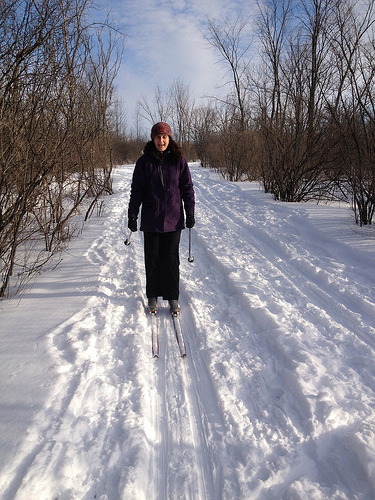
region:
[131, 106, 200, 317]
skier wearing black outfit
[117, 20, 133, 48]
white clouds in blue sky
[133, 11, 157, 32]
white clouds in blue sky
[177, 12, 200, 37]
white clouds in blue sky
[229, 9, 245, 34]
white clouds in blue sky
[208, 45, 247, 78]
white clouds in blue sky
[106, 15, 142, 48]
white clouds in blue sky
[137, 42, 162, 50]
white clouds in blue sky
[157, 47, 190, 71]
white clouds in blue sky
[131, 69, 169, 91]
white clouds in blue sky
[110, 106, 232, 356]
the woman is skiing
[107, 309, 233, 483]
lines are in the snow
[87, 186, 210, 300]
the woman is holding ski sticks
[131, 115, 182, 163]
the woman is smiling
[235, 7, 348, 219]
the trees are bare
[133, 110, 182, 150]
woman is wearing a hat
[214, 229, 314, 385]
foot prints in the snow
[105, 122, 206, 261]
the woman is wearing a coat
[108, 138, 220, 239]
the coat is purple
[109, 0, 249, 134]
the sky is partly cloudy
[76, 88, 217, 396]
a woman on skis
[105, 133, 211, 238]
a purple winter jacket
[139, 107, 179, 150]
a hat on her head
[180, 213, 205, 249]
black gloves on hands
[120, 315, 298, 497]
ski marks in the snow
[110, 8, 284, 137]
white clouds in the sky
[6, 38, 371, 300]
lots of bare trees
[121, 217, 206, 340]
black pants on woman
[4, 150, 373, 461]
snow covers the ground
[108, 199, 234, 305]
a ski pole in each hand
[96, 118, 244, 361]
This is a woman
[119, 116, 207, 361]
The woman is on skis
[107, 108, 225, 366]
The woman is skiing on snow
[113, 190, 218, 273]
She is holding ski poles in both hands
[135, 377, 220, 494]
There are ski tracks in the snow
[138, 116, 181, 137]
The woman is wearing a hat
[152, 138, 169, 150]
The woman's mouth is open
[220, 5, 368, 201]
The trees are brown and bare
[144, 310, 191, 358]
The skis are covered in snow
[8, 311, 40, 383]
This snow is untouched by people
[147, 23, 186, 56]
white clouds in blue sky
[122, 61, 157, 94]
white clouds in blue sky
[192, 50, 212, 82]
white clouds in blue sky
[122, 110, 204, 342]
skier in black outfit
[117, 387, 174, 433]
white snow on the ground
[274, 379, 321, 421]
white snow on the ground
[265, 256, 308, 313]
white snow on the ground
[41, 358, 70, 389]
white snow on the ground